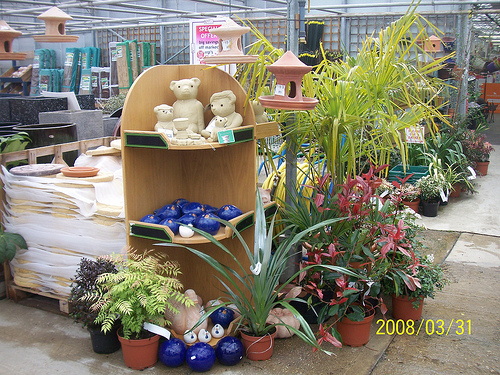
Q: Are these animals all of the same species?
A: Yes, all the animals are bears.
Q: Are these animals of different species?
A: No, all the animals are bears.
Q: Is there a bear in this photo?
A: Yes, there are bears.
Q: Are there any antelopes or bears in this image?
A: Yes, there are bears.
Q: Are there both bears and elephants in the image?
A: No, there are bears but no elephants.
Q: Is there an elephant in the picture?
A: No, there are no elephants.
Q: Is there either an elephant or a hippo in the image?
A: No, there are no elephants or hippoes.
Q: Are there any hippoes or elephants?
A: No, there are no elephants or hippoes.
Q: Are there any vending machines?
A: No, there are no vending machines.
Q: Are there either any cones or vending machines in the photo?
A: No, there are no vending machines or cones.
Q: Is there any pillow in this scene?
A: No, there are no pillows.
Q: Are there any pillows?
A: No, there are no pillows.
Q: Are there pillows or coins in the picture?
A: No, there are no pillows or coins.